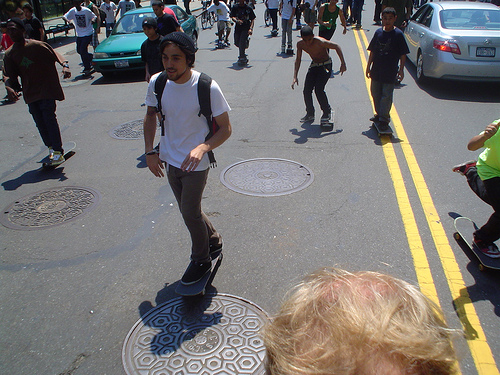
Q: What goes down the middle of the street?
A: Double yellow line.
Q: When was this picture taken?
A: Daytime.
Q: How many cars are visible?
A: Two.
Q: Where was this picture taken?
A: In the street.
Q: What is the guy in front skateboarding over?
A: Manhole cover.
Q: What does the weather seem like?
A: Warm and sunny.